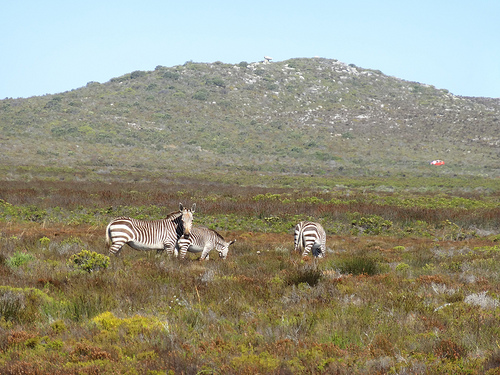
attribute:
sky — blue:
[0, 2, 498, 103]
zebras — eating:
[267, 212, 330, 255]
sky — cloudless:
[43, 6, 483, 117]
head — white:
[150, 205, 227, 258]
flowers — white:
[125, 283, 203, 326]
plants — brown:
[0, 178, 499, 225]